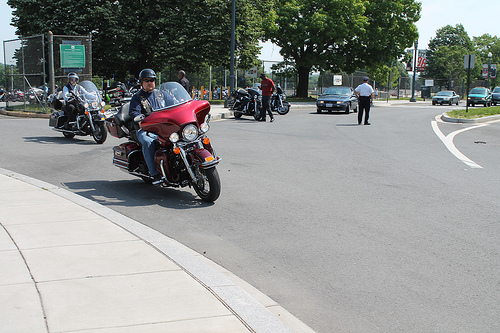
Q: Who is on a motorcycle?
A: A man.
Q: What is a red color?
A: Motorcycle.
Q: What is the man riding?
A: Bike.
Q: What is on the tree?
A: Leaves.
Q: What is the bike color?
A: Red.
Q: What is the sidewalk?
A: Paved.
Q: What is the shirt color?
A: Black.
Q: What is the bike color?
A: Red.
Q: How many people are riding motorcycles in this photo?
A: Two.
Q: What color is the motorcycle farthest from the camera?
A: Black.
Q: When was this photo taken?
A: Outside, during the daytime.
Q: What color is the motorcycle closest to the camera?
A: Red.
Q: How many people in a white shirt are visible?
A: One.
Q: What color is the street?
A: Gray.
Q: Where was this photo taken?
A: On a road, near traffic.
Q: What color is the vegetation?
A: Green.